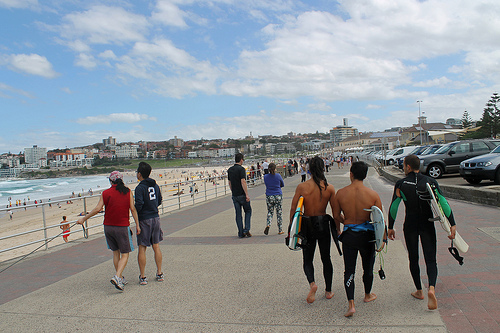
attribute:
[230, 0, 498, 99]
cloud — white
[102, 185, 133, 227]
shirt — red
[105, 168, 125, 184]
hat — pink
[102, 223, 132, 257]
shorts — grey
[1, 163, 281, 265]
beach — covered with sand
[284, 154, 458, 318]
they — walking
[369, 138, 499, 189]
cars — parked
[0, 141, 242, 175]
buildings — in the background, in the distance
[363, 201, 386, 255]
board — white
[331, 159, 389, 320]
surfer — shirtless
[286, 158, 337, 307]
surfer — shirtless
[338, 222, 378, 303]
wetsuit — black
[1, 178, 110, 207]
ocean — mildly rough, blue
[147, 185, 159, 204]
number 2 — white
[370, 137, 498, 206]
parking lot — to the right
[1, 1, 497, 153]
sky — partly cloudy, blue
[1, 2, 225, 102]
clouds — white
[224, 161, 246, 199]
t-shirt — black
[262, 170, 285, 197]
sweater — blue